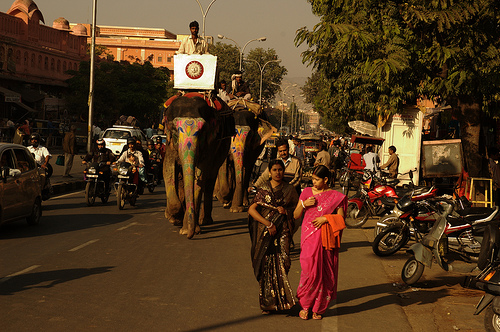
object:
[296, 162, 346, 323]
woman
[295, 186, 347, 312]
clothing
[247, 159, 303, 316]
woman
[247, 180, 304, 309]
clothing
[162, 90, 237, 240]
elephant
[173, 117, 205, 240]
trunk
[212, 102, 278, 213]
elephant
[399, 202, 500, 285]
motorcycle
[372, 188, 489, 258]
motorcycle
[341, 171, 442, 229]
motorcycle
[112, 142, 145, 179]
person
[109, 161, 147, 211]
motorcycle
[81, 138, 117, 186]
person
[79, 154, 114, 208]
motorcycle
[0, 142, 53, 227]
vehicle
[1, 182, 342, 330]
street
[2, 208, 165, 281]
line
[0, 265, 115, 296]
shadow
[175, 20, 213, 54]
man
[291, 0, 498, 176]
tree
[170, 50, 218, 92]
basket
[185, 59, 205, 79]
design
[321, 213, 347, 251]
fabric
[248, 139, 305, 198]
person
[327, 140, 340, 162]
person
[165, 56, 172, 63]
window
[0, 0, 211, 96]
building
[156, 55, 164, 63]
window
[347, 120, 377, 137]
umbrella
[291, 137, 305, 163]
person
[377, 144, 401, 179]
person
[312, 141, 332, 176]
person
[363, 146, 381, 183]
person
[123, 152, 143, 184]
person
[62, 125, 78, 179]
person